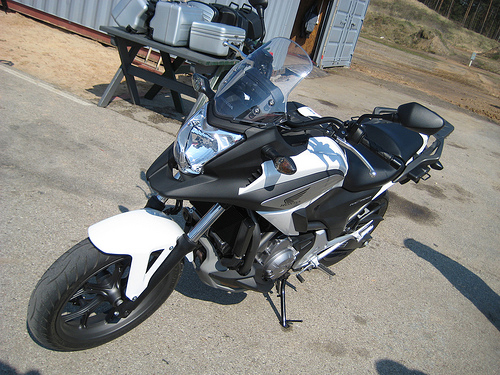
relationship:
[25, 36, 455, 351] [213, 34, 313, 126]
bike has windshield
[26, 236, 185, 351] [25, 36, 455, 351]
wheel on bike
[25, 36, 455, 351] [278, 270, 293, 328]
bike has kickstand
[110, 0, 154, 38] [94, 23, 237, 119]
container on picnic table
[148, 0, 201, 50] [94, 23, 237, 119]
container on picnic table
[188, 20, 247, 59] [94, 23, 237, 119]
container on picnic table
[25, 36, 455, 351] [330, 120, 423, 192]
bike has seat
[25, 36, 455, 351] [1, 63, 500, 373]
bike on road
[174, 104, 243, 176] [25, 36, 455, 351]
headlight on bike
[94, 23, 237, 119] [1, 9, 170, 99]
picnic table on dirt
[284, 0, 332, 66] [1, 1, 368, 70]
door of structure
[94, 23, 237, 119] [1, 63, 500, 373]
picnic table near road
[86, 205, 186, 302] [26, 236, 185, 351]
cap on wheel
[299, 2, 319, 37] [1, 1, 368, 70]
clothes in structure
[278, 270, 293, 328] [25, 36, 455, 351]
kickstand supports bike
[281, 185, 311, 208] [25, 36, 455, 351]
logo on bike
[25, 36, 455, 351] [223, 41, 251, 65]
bike has brake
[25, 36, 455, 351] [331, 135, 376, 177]
bike has brake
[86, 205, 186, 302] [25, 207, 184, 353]
cap on wheel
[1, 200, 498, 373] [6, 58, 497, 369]
shadows on pavement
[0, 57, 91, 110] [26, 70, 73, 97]
line showing edge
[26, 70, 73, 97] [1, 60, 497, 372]
edge of paving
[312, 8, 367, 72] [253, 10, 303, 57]
container beside door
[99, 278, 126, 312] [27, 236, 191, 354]
wheel cap on bike tire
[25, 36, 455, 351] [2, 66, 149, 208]
bike on road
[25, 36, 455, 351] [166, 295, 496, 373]
bike on road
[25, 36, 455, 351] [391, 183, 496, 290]
bike on road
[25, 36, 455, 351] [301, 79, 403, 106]
bike on road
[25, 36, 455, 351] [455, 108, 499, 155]
bike on road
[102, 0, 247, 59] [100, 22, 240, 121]
boxes on table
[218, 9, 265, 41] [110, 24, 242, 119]
bags on table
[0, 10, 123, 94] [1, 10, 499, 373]
soil on ground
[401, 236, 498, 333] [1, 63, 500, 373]
shadow on road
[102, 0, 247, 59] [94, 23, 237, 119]
boxes on picnic table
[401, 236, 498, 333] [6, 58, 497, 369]
shadow on pavement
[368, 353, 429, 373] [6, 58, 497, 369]
shadow on pavement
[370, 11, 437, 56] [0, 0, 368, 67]
dirt mound behind storage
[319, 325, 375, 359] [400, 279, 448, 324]
oil spots soak into pavement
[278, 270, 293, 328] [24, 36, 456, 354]
kickstand on motorcycle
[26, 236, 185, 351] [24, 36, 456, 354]
wheel of a motorcycle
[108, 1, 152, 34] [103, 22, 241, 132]
silver container on table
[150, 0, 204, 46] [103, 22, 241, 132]
silver container on table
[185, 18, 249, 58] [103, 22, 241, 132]
silver container on table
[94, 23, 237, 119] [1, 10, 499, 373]
picnic table on ground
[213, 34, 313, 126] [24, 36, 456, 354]
windshield on motorcycle